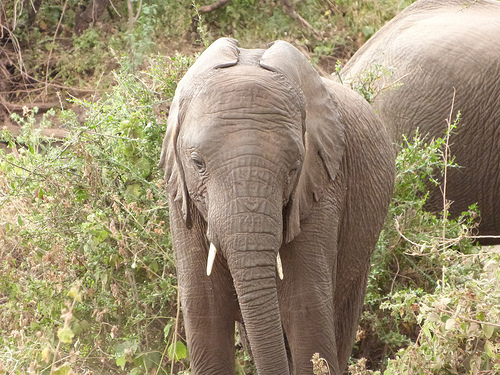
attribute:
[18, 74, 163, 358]
bushes — big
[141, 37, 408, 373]
elephant — grey, baby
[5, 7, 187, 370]
grass — green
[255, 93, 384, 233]
skin — grey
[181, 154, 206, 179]
elephant — baby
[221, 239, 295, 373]
trunk — grey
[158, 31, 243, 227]
ear — grey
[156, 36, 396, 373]
elephant — baby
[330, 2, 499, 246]
elephant — large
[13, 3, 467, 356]
area — wooded